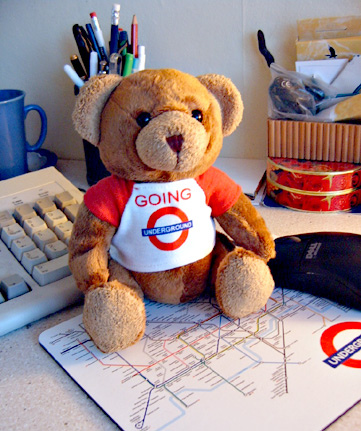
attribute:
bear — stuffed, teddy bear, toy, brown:
[69, 68, 277, 355]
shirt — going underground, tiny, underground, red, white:
[82, 165, 244, 273]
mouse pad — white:
[37, 283, 359, 430]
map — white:
[49, 283, 360, 431]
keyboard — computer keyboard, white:
[1, 166, 104, 339]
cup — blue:
[72, 84, 110, 186]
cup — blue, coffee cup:
[1, 88, 48, 179]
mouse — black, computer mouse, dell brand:
[270, 231, 360, 310]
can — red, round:
[265, 157, 361, 214]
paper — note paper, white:
[294, 58, 359, 108]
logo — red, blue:
[320, 320, 360, 370]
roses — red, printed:
[265, 158, 359, 211]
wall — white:
[1, 2, 360, 157]